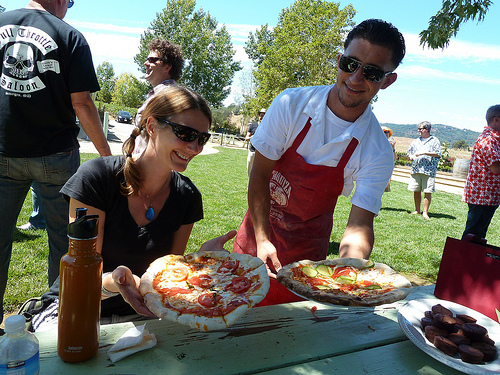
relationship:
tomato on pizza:
[198, 268, 205, 281] [185, 243, 246, 307]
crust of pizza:
[202, 309, 220, 329] [185, 243, 246, 307]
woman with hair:
[82, 69, 228, 337] [181, 88, 194, 101]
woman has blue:
[82, 69, 228, 337] [141, 187, 163, 223]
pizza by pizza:
[185, 243, 246, 307] [287, 247, 417, 309]